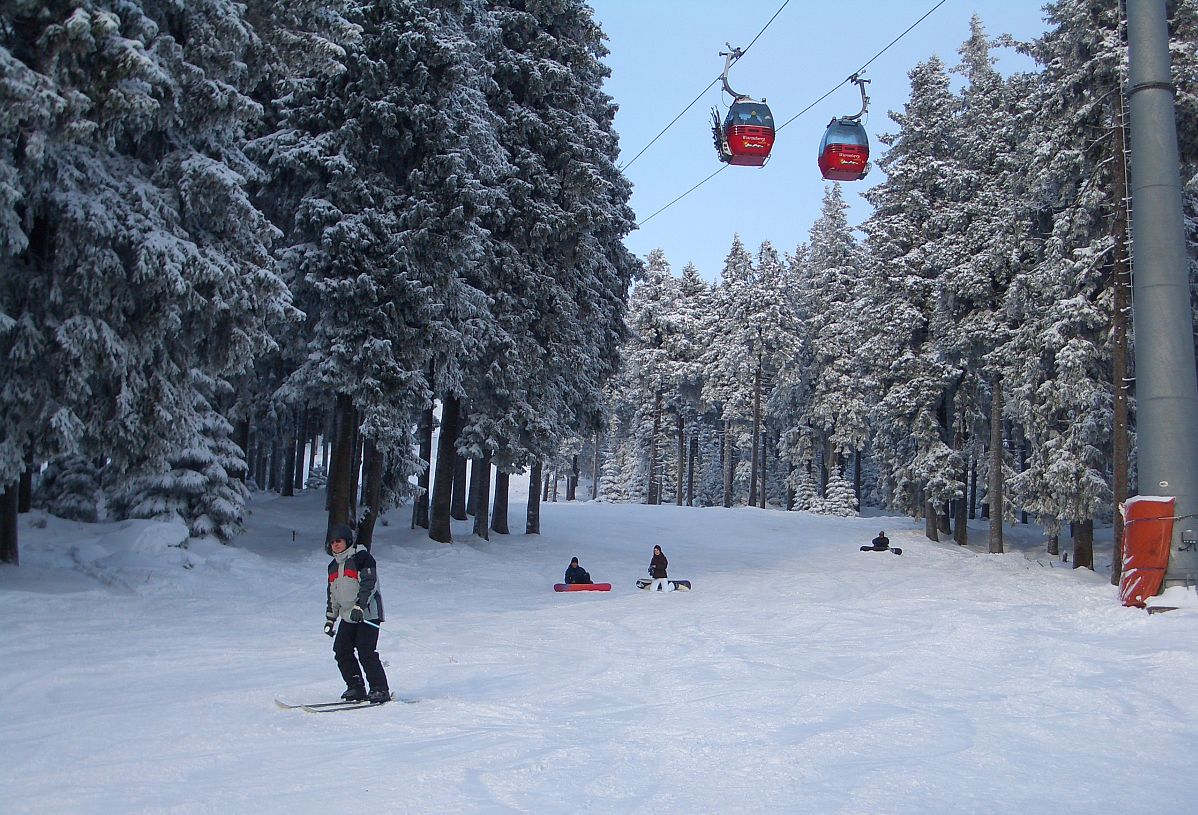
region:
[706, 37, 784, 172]
A red chairlift on a wire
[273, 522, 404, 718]
A skier in the snow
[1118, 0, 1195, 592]
A metal pole in the snow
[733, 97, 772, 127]
Window on a chairlift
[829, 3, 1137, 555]
Trees in a snowy mountain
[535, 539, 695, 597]
People sitting in the snow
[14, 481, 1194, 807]
Snow on the ground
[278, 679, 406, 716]
Skis on a skier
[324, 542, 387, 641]
A coat on a skier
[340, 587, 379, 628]
Gloves on a skier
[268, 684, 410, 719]
Person on skis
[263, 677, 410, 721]
Person is on skis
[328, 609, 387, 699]
Person wearing pants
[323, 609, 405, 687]
Person is wearing pants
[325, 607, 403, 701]
Person wearing black pants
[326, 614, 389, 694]
Person is wearing black pants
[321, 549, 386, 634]
Person wearing a jacket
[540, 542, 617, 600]
Person sitting on the snow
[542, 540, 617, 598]
Person is sitting on the snow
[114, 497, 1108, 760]
Ground is white color.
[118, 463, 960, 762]
Snow is in ground.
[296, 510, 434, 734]
Man is wearing black pant.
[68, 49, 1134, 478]
Pine trees are covered with snow.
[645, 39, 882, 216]
Cable car is red color.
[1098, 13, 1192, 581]
Pole is grey color.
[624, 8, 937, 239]
Cable wire is passing above the ground.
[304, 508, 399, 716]
a person is standing up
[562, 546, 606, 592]
a person is sitting down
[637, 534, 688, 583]
a person is sitting down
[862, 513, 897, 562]
a person is sitting down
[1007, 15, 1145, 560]
a tree in a field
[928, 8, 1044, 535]
a tree in a field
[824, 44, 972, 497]
a tree in a field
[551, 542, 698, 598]
two skiers resting along the path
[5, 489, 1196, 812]
well packed snow, perfect for skiing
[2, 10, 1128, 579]
snow covered evergreen trees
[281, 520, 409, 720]
solo skier sweeping along the trail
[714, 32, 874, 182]
ski trollies taking skiers up and down the mountain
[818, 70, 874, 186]
empty cable car returning to the bottom of the mountian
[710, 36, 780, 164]
Cable car taking skiers to the top of the mountian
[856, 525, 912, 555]
skier stops to watch the cable cars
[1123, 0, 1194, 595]
large sturdy car car support pole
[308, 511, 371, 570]
the head of a man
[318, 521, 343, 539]
the hat of a man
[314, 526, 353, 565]
the face of a man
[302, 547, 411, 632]
the jacket of a man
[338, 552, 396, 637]
the left arm of a man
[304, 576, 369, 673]
the right arm of a man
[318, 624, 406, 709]
the pants of a man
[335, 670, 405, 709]
the shoes of a man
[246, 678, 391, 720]
the skis of a man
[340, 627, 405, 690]
the left leg of a man